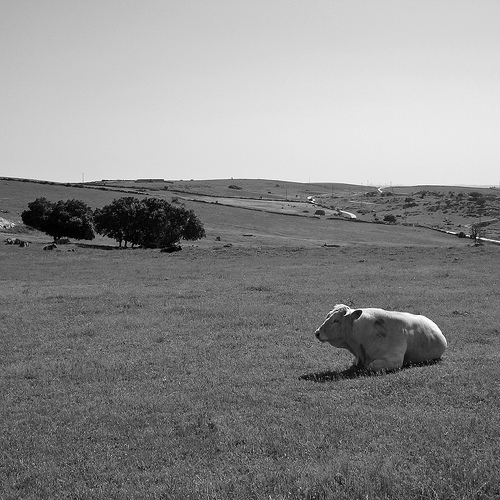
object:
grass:
[0, 173, 500, 500]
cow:
[317, 302, 449, 370]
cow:
[43, 243, 57, 250]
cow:
[17, 239, 30, 245]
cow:
[4, 236, 17, 243]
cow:
[160, 245, 183, 253]